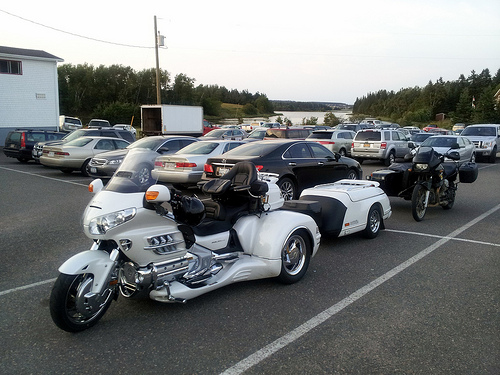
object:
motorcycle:
[48, 146, 393, 336]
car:
[198, 138, 361, 205]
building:
[1, 45, 73, 148]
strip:
[216, 282, 373, 375]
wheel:
[48, 259, 120, 333]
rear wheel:
[271, 230, 313, 284]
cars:
[348, 125, 416, 166]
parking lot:
[0, 118, 497, 375]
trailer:
[300, 177, 391, 243]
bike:
[400, 141, 462, 223]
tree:
[67, 61, 92, 111]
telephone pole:
[149, 21, 166, 106]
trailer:
[136, 102, 206, 135]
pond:
[272, 109, 342, 128]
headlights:
[145, 186, 160, 200]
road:
[0, 157, 499, 375]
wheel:
[273, 177, 301, 204]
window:
[306, 141, 331, 162]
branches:
[184, 77, 194, 82]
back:
[200, 155, 257, 177]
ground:
[0, 138, 498, 197]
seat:
[203, 161, 260, 209]